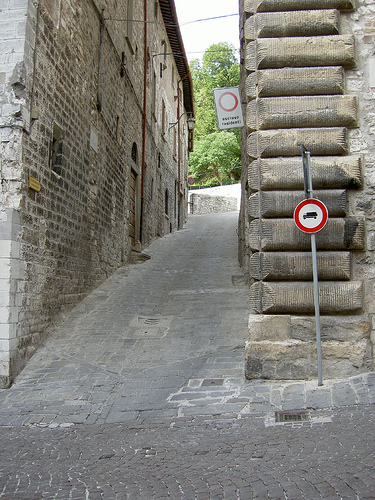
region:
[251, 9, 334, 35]
brick along side of wall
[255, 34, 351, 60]
brick along side of wall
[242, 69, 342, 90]
brick along side of wall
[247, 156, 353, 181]
brick along side of wall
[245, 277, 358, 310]
brick along side of wall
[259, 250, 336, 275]
brick along side of wall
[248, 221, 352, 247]
brick along side of wall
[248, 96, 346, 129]
brick along side of wall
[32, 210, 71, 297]
brick along side of wall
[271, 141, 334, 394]
a sign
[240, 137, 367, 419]
a sign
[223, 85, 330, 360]
a sign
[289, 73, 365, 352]
a sign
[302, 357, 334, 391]
base of long gray pole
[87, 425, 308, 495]
rough brick road by wall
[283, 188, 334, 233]
circular red and white sign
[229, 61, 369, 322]
long wooden wall for building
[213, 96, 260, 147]
dirty white sign thats above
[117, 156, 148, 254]
brown door on the left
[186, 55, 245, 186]
long green trees in the back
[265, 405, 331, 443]
opening leading to sewer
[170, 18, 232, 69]
electric cable lines above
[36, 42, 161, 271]
large brown brick wall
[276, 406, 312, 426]
drain on the ground.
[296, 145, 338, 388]
a sign on the sidewalk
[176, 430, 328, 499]
the brick layered road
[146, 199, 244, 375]
the alleyway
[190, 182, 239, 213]
wall on the other side of alley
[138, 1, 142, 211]
a red water drain pipe.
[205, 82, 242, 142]
a white sign on the building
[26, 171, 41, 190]
a yellow arrow sign on the wall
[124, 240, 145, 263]
steps to the doorway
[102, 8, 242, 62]
power lines from building to building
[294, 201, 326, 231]
Sign mounted on pole with truck.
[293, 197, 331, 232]
Round sign with red rim.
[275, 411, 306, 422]
Drainage grill on road.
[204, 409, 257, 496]
Road made of bricks.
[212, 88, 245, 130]
Sign mounted on stone wall.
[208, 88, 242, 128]
Rectangle sign with red circle inside.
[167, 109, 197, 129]
City light mounted on stone wall.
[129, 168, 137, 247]
Doorway off alley.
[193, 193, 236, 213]
Stone wall in background.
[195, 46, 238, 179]
Tall green tree in background.